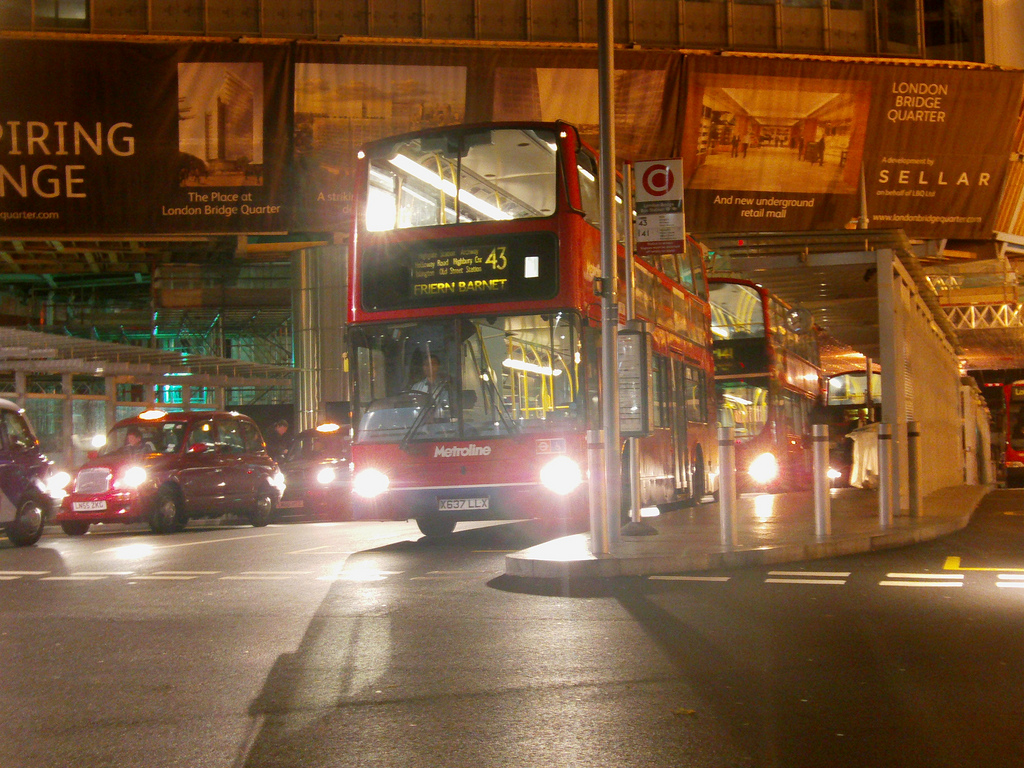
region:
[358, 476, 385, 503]
light on the bus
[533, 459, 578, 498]
light on the bus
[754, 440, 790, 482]
light on the bus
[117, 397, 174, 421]
light on the bus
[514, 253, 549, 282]
light on the bus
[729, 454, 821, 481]
light on the bus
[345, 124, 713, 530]
A red bus in the street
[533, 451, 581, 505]
A headlight on a bus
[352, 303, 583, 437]
Windshield on a bus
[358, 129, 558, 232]
A window on a bus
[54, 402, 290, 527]
A red car in the street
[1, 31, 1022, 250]
A banner in the city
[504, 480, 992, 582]
A curb in the city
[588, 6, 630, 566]
A pole on the curb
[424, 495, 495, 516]
License plate on a bus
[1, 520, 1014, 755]
paved road with short double-white stripes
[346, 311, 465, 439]
bus driver behind wheel through front window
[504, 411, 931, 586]
short metal poles around curve of median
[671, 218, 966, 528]
roof and side wall of bus shelter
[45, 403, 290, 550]
curved red car with bright headlights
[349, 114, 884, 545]
double-decker buses behind each other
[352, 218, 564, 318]
sign with route number and bus destination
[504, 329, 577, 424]
yellow poles inside bus for passengers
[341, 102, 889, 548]
The line of double decker buses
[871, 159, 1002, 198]
The word 'Sellar' on the black signs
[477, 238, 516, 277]
The number 43 on the front bus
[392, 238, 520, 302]
The words on the front bus' digital board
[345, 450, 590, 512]
The headlights of the front bus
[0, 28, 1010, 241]
The large black signs on the building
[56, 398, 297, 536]
The red car next to the lead bus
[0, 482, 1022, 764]
The road that all the cars are on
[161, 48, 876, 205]
The pictures on the large black sign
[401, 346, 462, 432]
The driver of the front bus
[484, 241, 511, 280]
number 43 on a bus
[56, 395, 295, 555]
red car on the street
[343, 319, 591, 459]
windshield of the bus at the intersection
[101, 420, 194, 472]
windshield of the red car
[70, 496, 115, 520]
license plate of the red car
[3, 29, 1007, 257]
banner of signs above the traffic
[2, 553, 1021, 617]
white dotted lines across the road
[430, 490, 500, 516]
license plate on the bus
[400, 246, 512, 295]
destination of the bus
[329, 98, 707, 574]
bus on the road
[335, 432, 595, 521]
lights on the bus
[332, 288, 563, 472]
front window on the bus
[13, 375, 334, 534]
cars on the road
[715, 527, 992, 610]
lines on the road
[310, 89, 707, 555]
the bus is red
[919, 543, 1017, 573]
yellow line on the road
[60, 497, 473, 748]
reflections on the road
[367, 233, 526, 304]
sign on the building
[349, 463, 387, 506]
bright light on the vehicle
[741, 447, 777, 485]
bright light on the vehicle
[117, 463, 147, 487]
bright light on the vehicle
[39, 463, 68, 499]
bright light on the vehicle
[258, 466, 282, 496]
bright light on the vehicle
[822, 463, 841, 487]
bright light on the vehicle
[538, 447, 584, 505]
bright light on the vehicle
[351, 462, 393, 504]
bright light on the vehicle